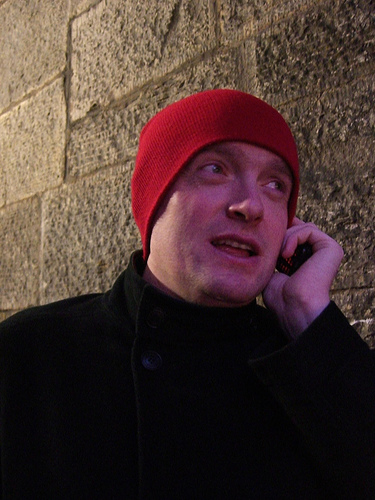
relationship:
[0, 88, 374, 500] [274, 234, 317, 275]
man on cellphone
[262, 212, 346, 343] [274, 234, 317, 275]
hand holding cellphone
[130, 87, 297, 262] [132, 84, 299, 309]
bennie on head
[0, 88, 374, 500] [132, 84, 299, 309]
man has head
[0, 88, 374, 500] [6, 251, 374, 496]
man wearing a coat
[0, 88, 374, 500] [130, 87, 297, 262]
man wearing a bennie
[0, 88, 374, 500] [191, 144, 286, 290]
man looking amused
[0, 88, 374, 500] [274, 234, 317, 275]
man talking on cellphone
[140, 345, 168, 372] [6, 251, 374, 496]
button on top of coat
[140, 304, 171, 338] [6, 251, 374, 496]
button on top of coat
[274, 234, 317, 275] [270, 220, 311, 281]
cellphone in use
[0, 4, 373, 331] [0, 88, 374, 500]
wall behind man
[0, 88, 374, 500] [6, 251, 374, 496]
man wearing coat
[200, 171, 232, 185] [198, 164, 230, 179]
bag under eye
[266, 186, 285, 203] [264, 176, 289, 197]
bag under eye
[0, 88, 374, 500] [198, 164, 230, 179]
man has eye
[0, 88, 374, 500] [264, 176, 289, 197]
man has eye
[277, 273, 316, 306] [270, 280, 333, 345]
bony prominence on wrist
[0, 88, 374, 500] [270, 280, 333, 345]
man has wrist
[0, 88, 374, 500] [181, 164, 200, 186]
man has crows feet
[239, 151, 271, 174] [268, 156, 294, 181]
hairs between eyebrow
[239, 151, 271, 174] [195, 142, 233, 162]
hairs between eyebrow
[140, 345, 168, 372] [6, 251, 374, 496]
button from coat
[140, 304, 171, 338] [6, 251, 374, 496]
button from coat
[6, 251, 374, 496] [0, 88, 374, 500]
coat for man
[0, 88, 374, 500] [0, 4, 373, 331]
man standing by wall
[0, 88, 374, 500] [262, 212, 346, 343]
man has hand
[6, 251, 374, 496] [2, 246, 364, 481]
coat for winter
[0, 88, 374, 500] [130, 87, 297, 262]
man wearing bennie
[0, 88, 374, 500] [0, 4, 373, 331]
man next to wall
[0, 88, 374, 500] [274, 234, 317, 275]
man using cellphone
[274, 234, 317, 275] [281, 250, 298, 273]
cellphone has buttons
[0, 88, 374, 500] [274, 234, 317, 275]
man holding cellphone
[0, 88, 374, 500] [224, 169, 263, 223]
man has nose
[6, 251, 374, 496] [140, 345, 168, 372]
coat has button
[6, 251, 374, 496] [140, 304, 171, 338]
coat has button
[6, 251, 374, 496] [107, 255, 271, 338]
coat has collar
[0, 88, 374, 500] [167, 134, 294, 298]
man has face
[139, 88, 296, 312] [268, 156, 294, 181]
man has eyebrow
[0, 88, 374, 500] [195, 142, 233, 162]
man has eyebrow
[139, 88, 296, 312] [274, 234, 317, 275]
man talking on cellphone